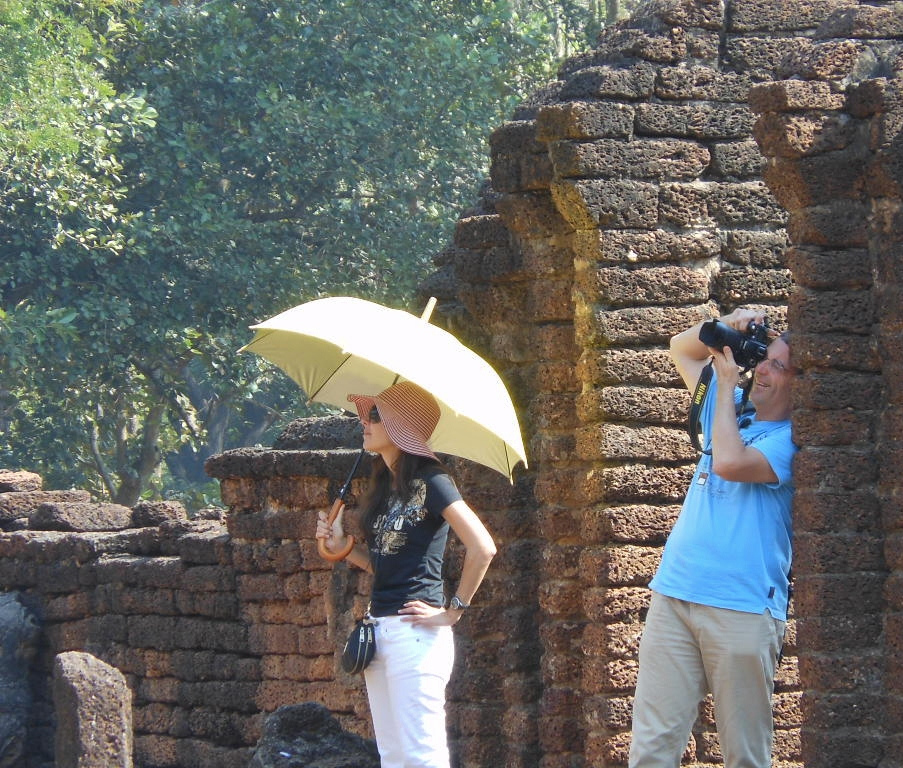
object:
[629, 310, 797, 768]
man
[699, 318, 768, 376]
camera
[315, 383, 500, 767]
woman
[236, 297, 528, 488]
umbrella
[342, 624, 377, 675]
bag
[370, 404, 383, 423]
shades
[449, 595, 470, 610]
watch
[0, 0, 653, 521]
tree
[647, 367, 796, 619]
shirt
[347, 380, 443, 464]
hat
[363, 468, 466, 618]
shirt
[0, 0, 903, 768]
scene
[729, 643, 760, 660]
object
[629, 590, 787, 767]
pants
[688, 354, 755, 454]
strap